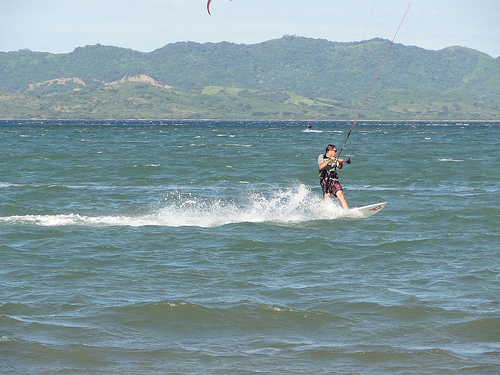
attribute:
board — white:
[326, 174, 416, 230]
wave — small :
[162, 197, 264, 229]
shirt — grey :
[316, 150, 341, 178]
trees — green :
[21, 43, 362, 113]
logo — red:
[370, 201, 385, 217]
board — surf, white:
[318, 198, 399, 218]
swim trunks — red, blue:
[318, 177, 343, 195]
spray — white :
[161, 173, 276, 235]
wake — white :
[346, 194, 386, 221]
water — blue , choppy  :
[403, 147, 426, 183]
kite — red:
[206, 0, 219, 21]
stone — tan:
[26, 72, 176, 92]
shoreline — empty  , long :
[316, 106, 408, 127]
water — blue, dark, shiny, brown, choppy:
[2, 118, 499, 370]